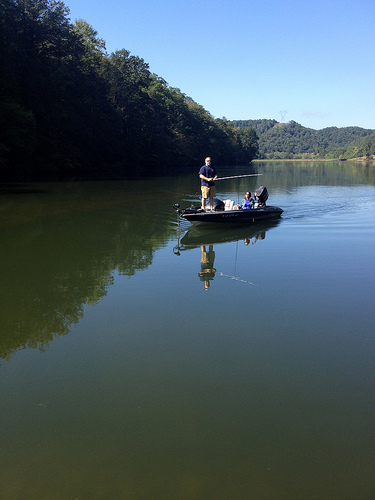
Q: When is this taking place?
A: Daytime.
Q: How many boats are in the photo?
A: One.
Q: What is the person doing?
A: Fishing.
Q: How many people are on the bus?
A: Two.